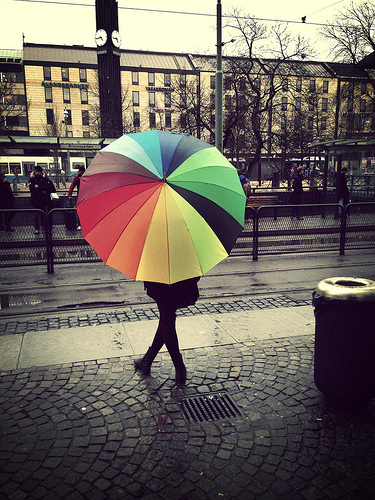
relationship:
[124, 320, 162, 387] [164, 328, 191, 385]
leg cross leg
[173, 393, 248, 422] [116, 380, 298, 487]
drain in ground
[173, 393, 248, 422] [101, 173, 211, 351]
drain behind woman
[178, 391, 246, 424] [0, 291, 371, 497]
metal grate on sidewalk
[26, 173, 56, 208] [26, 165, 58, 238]
coat on man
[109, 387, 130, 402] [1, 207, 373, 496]
brick on sidewalk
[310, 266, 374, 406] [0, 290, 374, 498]
trashcan on brick walkway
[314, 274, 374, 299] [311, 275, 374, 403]
top on trashcan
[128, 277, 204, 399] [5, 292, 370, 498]
woman by walkway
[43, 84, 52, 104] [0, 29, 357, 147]
window on building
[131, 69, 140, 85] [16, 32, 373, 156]
window on tan building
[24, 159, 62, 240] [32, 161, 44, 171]
person wears hat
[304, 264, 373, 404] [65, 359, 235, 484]
trash on sidewalk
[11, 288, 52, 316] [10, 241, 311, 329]
puddle on street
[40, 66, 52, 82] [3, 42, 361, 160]
window on building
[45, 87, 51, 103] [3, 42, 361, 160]
window on building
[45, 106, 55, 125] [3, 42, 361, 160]
window on building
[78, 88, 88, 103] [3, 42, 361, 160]
window on building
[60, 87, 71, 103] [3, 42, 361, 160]
window on building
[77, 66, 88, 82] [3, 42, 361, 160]
window on building